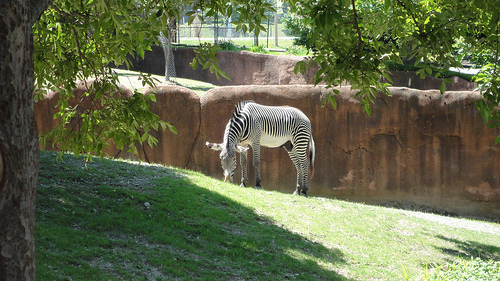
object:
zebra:
[204, 99, 316, 198]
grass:
[35, 150, 317, 280]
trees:
[0, 0, 278, 280]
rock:
[355, 115, 440, 178]